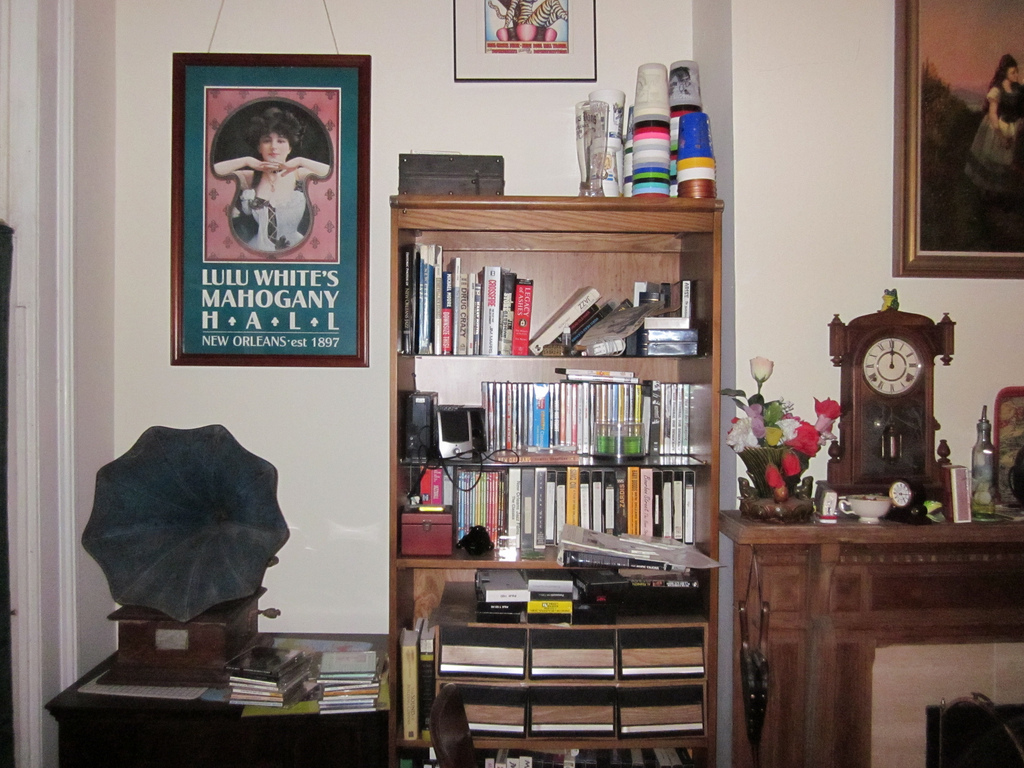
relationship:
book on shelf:
[510, 280, 530, 334] [409, 340, 713, 378]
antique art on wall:
[892, 0, 1024, 280] [737, 13, 1022, 478]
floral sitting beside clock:
[704, 343, 853, 528] [838, 290, 942, 511]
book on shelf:
[660, 469, 677, 545] [395, 197, 729, 766]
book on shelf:
[484, 261, 501, 354] [395, 197, 729, 766]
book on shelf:
[516, 272, 533, 352] [395, 197, 729, 766]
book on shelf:
[531, 278, 596, 355] [395, 197, 729, 766]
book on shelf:
[420, 237, 434, 348] [395, 197, 729, 766]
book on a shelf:
[664, 466, 684, 552] [393, 535, 725, 583]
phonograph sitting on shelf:
[78, 417, 291, 690] [42, 649, 404, 764]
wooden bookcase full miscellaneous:
[386, 197, 723, 766] [403, 235, 711, 766]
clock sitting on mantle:
[754, 262, 979, 509] [706, 509, 1018, 620]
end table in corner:
[48, 629, 394, 762] [99, 4, 144, 643]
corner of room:
[99, 4, 144, 643] [0, 0, 1024, 763]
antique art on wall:
[168, 58, 365, 366] [111, 10, 1022, 617]